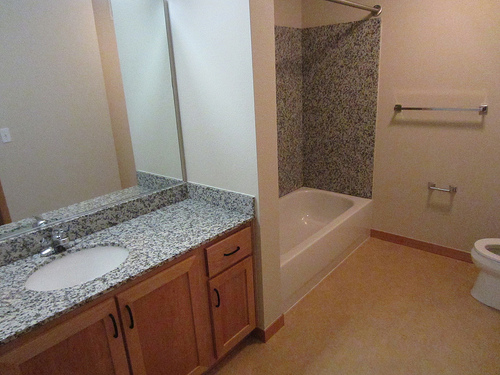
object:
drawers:
[0, 228, 258, 375]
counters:
[0, 196, 249, 343]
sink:
[23, 243, 129, 293]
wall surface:
[169, 0, 266, 334]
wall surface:
[370, 3, 498, 255]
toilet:
[469, 237, 500, 312]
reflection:
[33, 215, 48, 226]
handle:
[428, 182, 457, 194]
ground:
[468, 187, 500, 205]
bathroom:
[0, 0, 500, 375]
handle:
[394, 104, 488, 115]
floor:
[201, 237, 500, 375]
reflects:
[52, 79, 134, 180]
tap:
[40, 229, 81, 257]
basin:
[279, 186, 373, 314]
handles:
[109, 314, 119, 338]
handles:
[125, 305, 135, 330]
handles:
[214, 288, 221, 307]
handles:
[224, 246, 241, 256]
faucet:
[37, 220, 82, 258]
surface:
[142, 185, 201, 242]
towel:
[397, 87, 477, 148]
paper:
[426, 181, 457, 212]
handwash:
[5, 113, 205, 271]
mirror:
[0, 0, 186, 239]